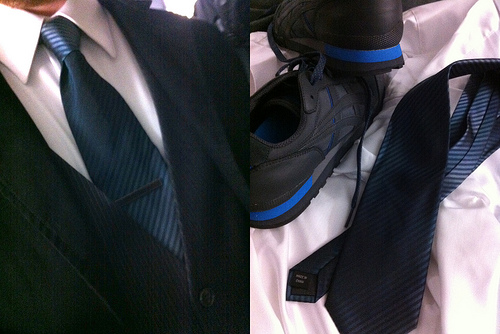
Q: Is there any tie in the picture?
A: Yes, there is a tie.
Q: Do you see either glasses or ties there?
A: Yes, there is a tie.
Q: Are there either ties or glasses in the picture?
A: Yes, there is a tie.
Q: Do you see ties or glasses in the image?
A: Yes, there is a tie.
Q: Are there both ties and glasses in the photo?
A: No, there is a tie but no glasses.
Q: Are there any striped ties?
A: Yes, there is a striped tie.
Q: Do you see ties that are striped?
A: Yes, there is a tie that is striped.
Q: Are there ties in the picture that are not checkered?
A: Yes, there is a striped tie.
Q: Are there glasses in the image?
A: No, there are no glasses.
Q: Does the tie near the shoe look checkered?
A: No, the necktie is striped.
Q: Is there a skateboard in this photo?
A: No, there are no skateboards.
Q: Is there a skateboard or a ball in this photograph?
A: No, there are no skateboards or balls.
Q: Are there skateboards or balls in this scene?
A: No, there are no skateboards or balls.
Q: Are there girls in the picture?
A: No, there are no girls.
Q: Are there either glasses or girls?
A: No, there are no girls or glasses.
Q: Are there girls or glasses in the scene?
A: No, there are no girls or glasses.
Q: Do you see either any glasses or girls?
A: No, there are no girls or glasses.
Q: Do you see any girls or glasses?
A: No, there are no girls or glasses.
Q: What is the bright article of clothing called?
A: The clothing item is a shirt.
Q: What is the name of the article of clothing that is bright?
A: The clothing item is a shirt.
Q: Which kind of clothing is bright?
A: The clothing is a shirt.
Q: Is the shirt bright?
A: Yes, the shirt is bright.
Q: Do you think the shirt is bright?
A: Yes, the shirt is bright.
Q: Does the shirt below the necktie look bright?
A: Yes, the shirt is bright.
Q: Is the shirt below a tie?
A: Yes, the shirt is below a tie.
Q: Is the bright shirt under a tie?
A: Yes, the shirt is under a tie.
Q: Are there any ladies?
A: No, there are no ladies.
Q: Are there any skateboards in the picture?
A: No, there are no skateboards.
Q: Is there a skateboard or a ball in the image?
A: No, there are no skateboards or balls.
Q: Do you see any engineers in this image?
A: No, there are no engineers.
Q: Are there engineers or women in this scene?
A: No, there are no engineers or women.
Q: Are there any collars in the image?
A: Yes, there is a collar.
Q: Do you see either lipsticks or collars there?
A: Yes, there is a collar.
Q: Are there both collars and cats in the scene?
A: No, there is a collar but no cats.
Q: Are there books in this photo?
A: No, there are no books.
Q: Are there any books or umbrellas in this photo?
A: No, there are no books or umbrellas.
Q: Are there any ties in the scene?
A: Yes, there is a tie.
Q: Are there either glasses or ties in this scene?
A: Yes, there is a tie.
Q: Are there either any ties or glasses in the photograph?
A: Yes, there is a tie.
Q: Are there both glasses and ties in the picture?
A: No, there is a tie but no glasses.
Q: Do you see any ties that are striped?
A: Yes, there is a striped tie.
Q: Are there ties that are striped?
A: Yes, there is a tie that is striped.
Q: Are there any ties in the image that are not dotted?
A: Yes, there is a striped tie.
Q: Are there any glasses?
A: No, there are no glasses.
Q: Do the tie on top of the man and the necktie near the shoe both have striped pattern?
A: Yes, both the tie and the necktie are striped.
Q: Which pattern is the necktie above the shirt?
A: The tie is striped.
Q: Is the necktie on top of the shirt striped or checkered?
A: The necktie is striped.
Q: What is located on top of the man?
A: The tie is on top of the man.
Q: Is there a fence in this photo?
A: No, there are no fences.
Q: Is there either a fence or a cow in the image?
A: No, there are no fences or cows.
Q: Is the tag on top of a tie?
A: Yes, the tag is on top of a tie.